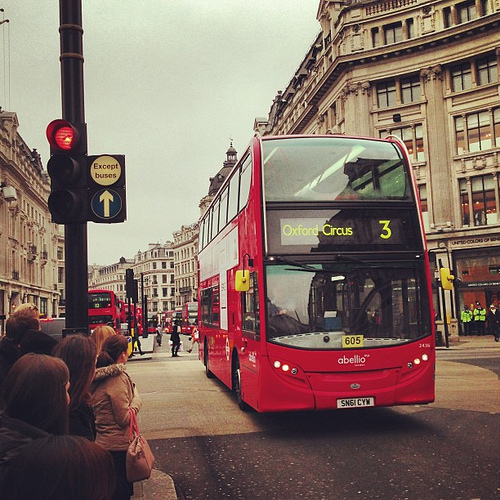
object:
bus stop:
[45, 0, 127, 336]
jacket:
[86, 362, 144, 450]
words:
[283, 217, 391, 241]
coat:
[458, 309, 473, 323]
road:
[132, 322, 499, 498]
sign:
[88, 185, 123, 220]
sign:
[88, 153, 121, 187]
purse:
[125, 406, 155, 481]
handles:
[120, 395, 150, 437]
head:
[95, 331, 128, 366]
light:
[54, 127, 76, 149]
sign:
[85, 153, 126, 223]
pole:
[58, 0, 88, 338]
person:
[85, 333, 154, 498]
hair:
[95, 334, 128, 369]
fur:
[91, 362, 126, 379]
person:
[0, 350, 117, 499]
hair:
[0, 350, 70, 434]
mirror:
[232, 268, 248, 291]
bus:
[194, 131, 454, 412]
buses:
[87, 287, 120, 332]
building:
[1, 107, 74, 337]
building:
[189, 0, 498, 352]